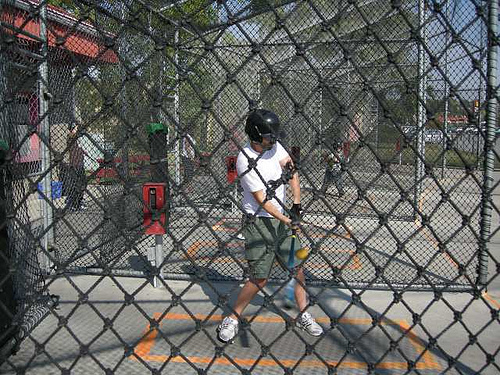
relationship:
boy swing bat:
[217, 109, 326, 342] [280, 228, 299, 313]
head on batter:
[242, 109, 290, 159] [217, 103, 322, 347]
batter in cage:
[217, 103, 322, 347] [51, 28, 487, 365]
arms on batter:
[241, 171, 310, 221] [234, 102, 309, 321]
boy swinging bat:
[217, 109, 326, 342] [282, 229, 296, 311]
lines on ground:
[123, 314, 423, 363] [5, 159, 498, 373]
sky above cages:
[217, 5, 480, 123] [5, 1, 497, 373]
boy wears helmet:
[217, 109, 326, 342] [242, 107, 280, 137]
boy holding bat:
[217, 109, 326, 342] [281, 231, 299, 309]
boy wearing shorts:
[235, 103, 311, 275] [241, 210, 306, 278]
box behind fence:
[142, 181, 169, 231] [1, 0, 499, 374]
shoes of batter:
[217, 312, 324, 342] [217, 103, 322, 347]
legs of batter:
[214, 243, 331, 346] [217, 103, 322, 347]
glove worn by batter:
[285, 199, 305, 227] [212, 102, 328, 350]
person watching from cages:
[64, 123, 90, 212] [0, 0, 121, 277]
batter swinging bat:
[217, 103, 322, 347] [284, 219, 303, 319]